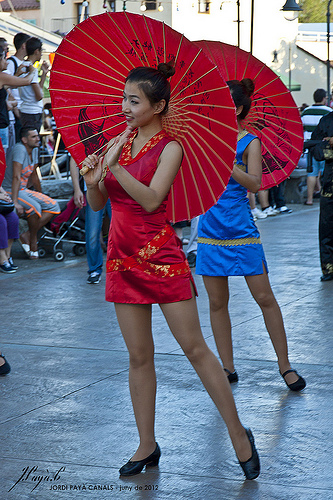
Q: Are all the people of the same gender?
A: No, they are both male and female.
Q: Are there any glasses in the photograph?
A: No, there are no glasses.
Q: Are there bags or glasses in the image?
A: No, there are no glasses or bags.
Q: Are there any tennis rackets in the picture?
A: No, there are no tennis rackets.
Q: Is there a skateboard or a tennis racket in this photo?
A: No, there are no rackets or skateboards.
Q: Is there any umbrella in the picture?
A: Yes, there is an umbrella.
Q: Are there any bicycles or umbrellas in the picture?
A: Yes, there is an umbrella.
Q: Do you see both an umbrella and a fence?
A: No, there is an umbrella but no fences.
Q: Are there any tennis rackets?
A: No, there are no tennis rackets.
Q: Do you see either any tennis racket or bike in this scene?
A: No, there are no rackets or bikes.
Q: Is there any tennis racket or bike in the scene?
A: No, there are no rackets or bikes.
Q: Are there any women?
A: Yes, there is a woman.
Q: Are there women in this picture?
A: Yes, there is a woman.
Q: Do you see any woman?
A: Yes, there is a woman.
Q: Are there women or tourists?
A: Yes, there is a woman.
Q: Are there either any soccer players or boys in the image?
A: No, there are no boys or soccer players.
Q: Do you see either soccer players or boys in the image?
A: No, there are no boys or soccer players.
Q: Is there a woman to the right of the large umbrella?
A: Yes, there is a woman to the right of the umbrella.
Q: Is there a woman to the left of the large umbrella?
A: No, the woman is to the right of the umbrella.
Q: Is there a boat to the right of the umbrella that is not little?
A: No, there is a woman to the right of the umbrella.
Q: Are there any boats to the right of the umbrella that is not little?
A: No, there is a woman to the right of the umbrella.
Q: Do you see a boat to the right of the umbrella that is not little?
A: No, there is a woman to the right of the umbrella.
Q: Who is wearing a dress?
A: The woman is wearing a dress.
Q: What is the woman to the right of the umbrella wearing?
A: The woman is wearing a dress.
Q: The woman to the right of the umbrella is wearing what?
A: The woman is wearing a dress.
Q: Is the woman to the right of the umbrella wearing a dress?
A: Yes, the woman is wearing a dress.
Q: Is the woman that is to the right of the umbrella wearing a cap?
A: No, the woman is wearing a dress.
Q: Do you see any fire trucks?
A: No, there are no fire trucks.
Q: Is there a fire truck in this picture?
A: No, there are no fire trucks.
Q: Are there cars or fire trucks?
A: No, there are no fire trucks or cars.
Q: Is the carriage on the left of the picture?
A: Yes, the carriage is on the left of the image.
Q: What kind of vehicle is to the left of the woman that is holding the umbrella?
A: The vehicle is a carriage.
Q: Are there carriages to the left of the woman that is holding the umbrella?
A: Yes, there is a carriage to the left of the woman.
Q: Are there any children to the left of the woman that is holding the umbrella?
A: No, there is a carriage to the left of the woman.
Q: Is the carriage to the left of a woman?
A: Yes, the carriage is to the left of a woman.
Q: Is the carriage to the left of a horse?
A: No, the carriage is to the left of a woman.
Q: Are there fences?
A: No, there are no fences.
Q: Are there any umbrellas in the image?
A: Yes, there is an umbrella.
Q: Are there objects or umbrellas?
A: Yes, there is an umbrella.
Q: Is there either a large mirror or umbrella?
A: Yes, there is a large umbrella.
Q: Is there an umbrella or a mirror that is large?
A: Yes, the umbrella is large.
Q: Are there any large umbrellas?
A: Yes, there is a large umbrella.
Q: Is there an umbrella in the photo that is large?
A: Yes, there is an umbrella that is large.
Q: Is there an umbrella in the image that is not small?
A: Yes, there is a large umbrella.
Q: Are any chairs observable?
A: No, there are no chairs.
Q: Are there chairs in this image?
A: No, there are no chairs.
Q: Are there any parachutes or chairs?
A: No, there are no chairs or parachutes.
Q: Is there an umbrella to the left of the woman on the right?
A: Yes, there is an umbrella to the left of the woman.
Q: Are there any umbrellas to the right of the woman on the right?
A: No, the umbrella is to the left of the woman.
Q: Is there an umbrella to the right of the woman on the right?
A: No, the umbrella is to the left of the woman.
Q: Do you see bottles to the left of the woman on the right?
A: No, there is an umbrella to the left of the woman.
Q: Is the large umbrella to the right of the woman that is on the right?
A: No, the umbrella is to the left of the woman.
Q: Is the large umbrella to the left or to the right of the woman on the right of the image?
A: The umbrella is to the left of the woman.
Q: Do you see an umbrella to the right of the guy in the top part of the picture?
A: Yes, there is an umbrella to the right of the guy.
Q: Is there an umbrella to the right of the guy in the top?
A: Yes, there is an umbrella to the right of the guy.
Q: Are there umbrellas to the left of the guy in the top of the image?
A: No, the umbrella is to the right of the guy.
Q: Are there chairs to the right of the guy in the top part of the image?
A: No, there is an umbrella to the right of the guy.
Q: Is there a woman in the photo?
A: Yes, there is a woman.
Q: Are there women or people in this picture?
A: Yes, there is a woman.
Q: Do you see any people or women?
A: Yes, there is a woman.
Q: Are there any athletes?
A: No, there are no athletes.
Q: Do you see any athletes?
A: No, there are no athletes.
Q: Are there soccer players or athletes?
A: No, there are no athletes or soccer players.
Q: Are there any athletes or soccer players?
A: No, there are no athletes or soccer players.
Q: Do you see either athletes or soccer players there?
A: No, there are no athletes or soccer players.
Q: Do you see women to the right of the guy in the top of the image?
A: Yes, there is a woman to the right of the guy.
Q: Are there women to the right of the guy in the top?
A: Yes, there is a woman to the right of the guy.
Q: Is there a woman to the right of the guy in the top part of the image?
A: Yes, there is a woman to the right of the guy.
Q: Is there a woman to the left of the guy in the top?
A: No, the woman is to the right of the guy.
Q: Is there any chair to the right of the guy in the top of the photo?
A: No, there is a woman to the right of the guy.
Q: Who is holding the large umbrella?
A: The woman is holding the umbrella.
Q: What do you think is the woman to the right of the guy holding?
A: The woman is holding the umbrella.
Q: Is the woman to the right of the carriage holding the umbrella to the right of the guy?
A: Yes, the woman is holding the umbrella.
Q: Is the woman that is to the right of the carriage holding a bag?
A: No, the woman is holding the umbrella.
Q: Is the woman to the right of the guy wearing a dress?
A: Yes, the woman is wearing a dress.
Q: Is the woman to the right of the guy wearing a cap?
A: No, the woman is wearing a dress.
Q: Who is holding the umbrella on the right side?
A: The woman is holding the umbrella.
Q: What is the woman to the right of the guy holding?
A: The woman is holding the umbrella.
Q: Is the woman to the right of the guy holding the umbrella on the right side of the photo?
A: Yes, the woman is holding the umbrella.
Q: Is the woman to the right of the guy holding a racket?
A: No, the woman is holding the umbrella.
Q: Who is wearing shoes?
A: The woman is wearing shoes.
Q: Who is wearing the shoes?
A: The woman is wearing shoes.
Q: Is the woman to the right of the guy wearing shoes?
A: Yes, the woman is wearing shoes.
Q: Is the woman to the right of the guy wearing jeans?
A: No, the woman is wearing shoes.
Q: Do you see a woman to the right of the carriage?
A: Yes, there is a woman to the right of the carriage.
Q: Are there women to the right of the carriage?
A: Yes, there is a woman to the right of the carriage.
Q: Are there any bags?
A: No, there are no bags.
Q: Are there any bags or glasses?
A: No, there are no bags or glasses.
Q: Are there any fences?
A: No, there are no fences.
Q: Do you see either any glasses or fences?
A: No, there are no fences or glasses.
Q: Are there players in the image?
A: No, there are no players.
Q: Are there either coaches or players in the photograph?
A: No, there are no players or coaches.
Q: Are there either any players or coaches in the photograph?
A: No, there are no players or coaches.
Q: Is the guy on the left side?
A: Yes, the guy is on the left of the image.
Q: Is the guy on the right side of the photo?
A: No, the guy is on the left of the image.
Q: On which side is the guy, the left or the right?
A: The guy is on the left of the image.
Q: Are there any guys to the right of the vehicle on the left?
A: Yes, there is a guy to the right of the carriage.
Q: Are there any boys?
A: No, there are no boys.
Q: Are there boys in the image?
A: No, there are no boys.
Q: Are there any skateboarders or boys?
A: No, there are no boys or skateboarders.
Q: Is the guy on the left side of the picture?
A: Yes, the guy is on the left of the image.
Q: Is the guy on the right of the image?
A: No, the guy is on the left of the image.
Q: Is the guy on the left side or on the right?
A: The guy is on the left of the image.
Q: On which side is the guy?
A: The guy is on the left of the image.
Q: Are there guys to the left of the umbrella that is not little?
A: Yes, there is a guy to the left of the umbrella.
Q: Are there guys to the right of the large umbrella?
A: No, the guy is to the left of the umbrella.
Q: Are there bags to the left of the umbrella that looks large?
A: No, there is a guy to the left of the umbrella.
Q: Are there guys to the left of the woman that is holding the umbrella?
A: Yes, there is a guy to the left of the woman.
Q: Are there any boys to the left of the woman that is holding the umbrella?
A: No, there is a guy to the left of the woman.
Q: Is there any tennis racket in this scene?
A: No, there are no rackets.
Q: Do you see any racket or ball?
A: No, there are no rackets or balls.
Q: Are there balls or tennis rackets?
A: No, there are no tennis rackets or balls.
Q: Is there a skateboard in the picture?
A: No, there are no skateboards.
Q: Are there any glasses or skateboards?
A: No, there are no skateboards or glasses.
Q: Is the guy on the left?
A: Yes, the guy is on the left of the image.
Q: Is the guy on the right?
A: No, the guy is on the left of the image.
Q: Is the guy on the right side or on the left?
A: The guy is on the left of the image.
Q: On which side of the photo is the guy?
A: The guy is on the left of the image.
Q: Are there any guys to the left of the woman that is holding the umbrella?
A: Yes, there is a guy to the left of the woman.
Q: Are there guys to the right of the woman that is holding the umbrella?
A: No, the guy is to the left of the woman.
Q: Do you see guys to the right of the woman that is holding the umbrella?
A: No, the guy is to the left of the woman.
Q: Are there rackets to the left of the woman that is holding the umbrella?
A: No, there is a guy to the left of the woman.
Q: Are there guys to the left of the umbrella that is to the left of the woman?
A: Yes, there is a guy to the left of the umbrella.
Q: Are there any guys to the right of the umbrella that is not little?
A: No, the guy is to the left of the umbrella.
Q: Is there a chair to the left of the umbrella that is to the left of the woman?
A: No, there is a guy to the left of the umbrella.